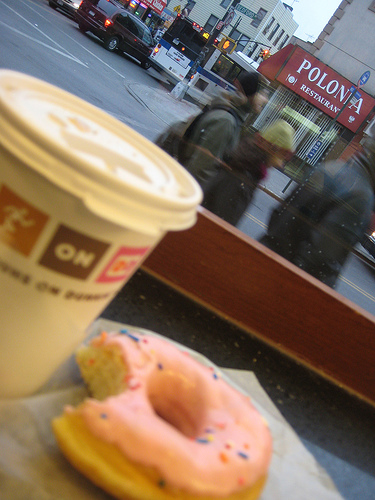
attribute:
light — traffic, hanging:
[257, 46, 272, 61]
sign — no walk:
[214, 35, 237, 54]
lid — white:
[0, 68, 202, 233]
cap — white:
[251, 114, 309, 163]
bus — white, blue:
[132, 18, 279, 127]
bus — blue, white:
[140, 9, 242, 124]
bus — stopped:
[151, 29, 275, 113]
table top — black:
[17, 360, 372, 493]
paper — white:
[8, 427, 55, 475]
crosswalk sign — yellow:
[215, 34, 236, 53]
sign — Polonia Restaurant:
[275, 42, 373, 137]